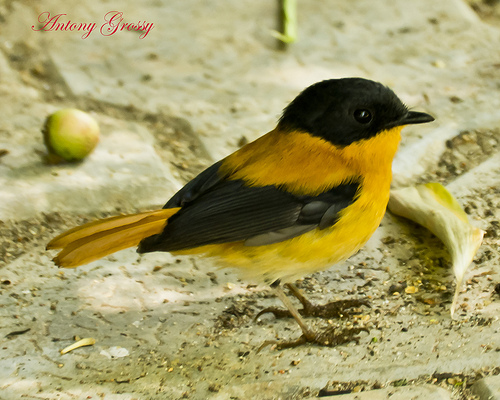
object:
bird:
[44, 78, 435, 354]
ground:
[1, 2, 500, 400]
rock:
[166, 271, 445, 398]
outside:
[1, 2, 500, 399]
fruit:
[42, 108, 100, 161]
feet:
[255, 304, 372, 350]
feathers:
[137, 157, 363, 256]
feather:
[46, 206, 182, 270]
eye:
[354, 108, 372, 125]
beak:
[401, 111, 434, 126]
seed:
[158, 350, 232, 383]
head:
[277, 78, 437, 163]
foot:
[254, 297, 370, 323]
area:
[51, 280, 491, 400]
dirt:
[192, 278, 499, 400]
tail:
[46, 207, 180, 269]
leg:
[271, 285, 307, 334]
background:
[1, 1, 499, 175]